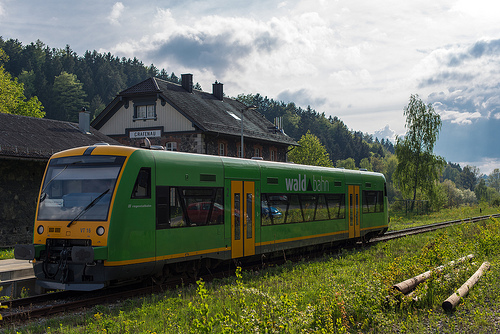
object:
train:
[28, 137, 389, 292]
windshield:
[36, 154, 127, 221]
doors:
[231, 180, 256, 259]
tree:
[392, 93, 445, 213]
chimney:
[211, 80, 224, 101]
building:
[0, 73, 302, 251]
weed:
[20, 105, 39, 113]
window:
[155, 185, 225, 230]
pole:
[390, 253, 475, 293]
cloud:
[177, 19, 301, 52]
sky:
[453, 130, 488, 147]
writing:
[284, 173, 331, 192]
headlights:
[35, 224, 105, 236]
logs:
[440, 261, 491, 309]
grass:
[339, 264, 374, 284]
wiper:
[66, 189, 111, 229]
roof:
[192, 98, 228, 116]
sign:
[127, 129, 161, 139]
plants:
[422, 244, 436, 267]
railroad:
[19, 291, 54, 318]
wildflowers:
[20, 105, 41, 115]